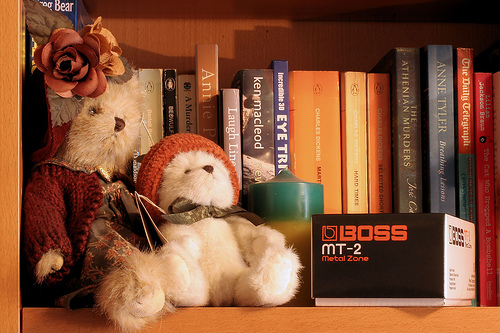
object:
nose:
[199, 162, 216, 172]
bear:
[93, 130, 301, 328]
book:
[341, 68, 369, 218]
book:
[426, 42, 461, 218]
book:
[455, 42, 478, 224]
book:
[221, 85, 246, 190]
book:
[194, 42, 222, 148]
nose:
[111, 117, 130, 132]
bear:
[19, 77, 175, 328]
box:
[309, 212, 476, 311]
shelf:
[22, 306, 500, 332]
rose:
[27, 24, 107, 102]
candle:
[243, 165, 332, 310]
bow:
[163, 197, 266, 226]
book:
[238, 62, 272, 189]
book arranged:
[286, 69, 340, 222]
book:
[471, 70, 500, 308]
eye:
[83, 106, 102, 120]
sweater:
[19, 154, 143, 291]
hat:
[135, 132, 243, 226]